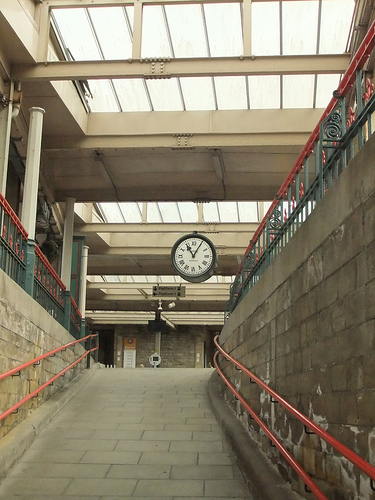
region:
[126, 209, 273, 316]
A large clock hanging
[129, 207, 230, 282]
the clock arrows are black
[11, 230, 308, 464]
this is a ramp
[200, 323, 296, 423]
the rails are red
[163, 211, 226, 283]
the numbers are roman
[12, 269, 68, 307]
fence is green and red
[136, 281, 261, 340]
this is a train station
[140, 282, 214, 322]
signs to the platforms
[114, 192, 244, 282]
the windows are skylights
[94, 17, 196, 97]
steel beams are tan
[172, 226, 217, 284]
The hanging clock that is black and white.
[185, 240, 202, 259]
The hands on the hanging clock.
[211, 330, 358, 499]
The red railing on the right side of the walkway.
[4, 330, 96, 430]
The red railing on the left side of the walkway.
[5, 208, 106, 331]
The red and green wrought iron gate on the left side platform.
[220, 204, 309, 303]
The red and green wrought iron gate on the right side of the top platform.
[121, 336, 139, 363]
The orange and white sign against the wall.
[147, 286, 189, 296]
The hanging black and white sign behind the clock.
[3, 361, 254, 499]
The walkway leading up to the clock.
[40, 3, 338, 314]
The skylight ceiling for natural lighting.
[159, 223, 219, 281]
A clock hanging down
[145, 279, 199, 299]
Sign to direct people to platforms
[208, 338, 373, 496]
red hand railing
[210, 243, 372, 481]
A stone wall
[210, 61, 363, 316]
green and red hand railing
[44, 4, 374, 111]
Windows on the roof to let in light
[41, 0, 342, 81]
A steel support beam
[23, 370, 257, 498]
a ramp leading to the main level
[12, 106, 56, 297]
a support column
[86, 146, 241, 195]
lights on the ceiling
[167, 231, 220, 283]
Clock hanging from above.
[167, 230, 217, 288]
The clock face is white.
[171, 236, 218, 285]
Numbers on the clock are black.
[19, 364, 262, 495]
Concrete block walkway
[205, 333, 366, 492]
Hand rails are red.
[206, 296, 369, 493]
Walls made of concrete block.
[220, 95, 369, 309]
Metal fence lining the wall.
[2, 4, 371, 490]
Nobody shown in the photo.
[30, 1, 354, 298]
Photo taken during the day.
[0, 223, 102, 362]
The fencing is green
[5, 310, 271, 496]
a walkway leading upward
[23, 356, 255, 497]
the walkway is made of bricks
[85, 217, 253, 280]
a clock hangs from an above beam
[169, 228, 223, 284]
the clock shows the time of 11:05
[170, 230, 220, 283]
the clock has roman numerals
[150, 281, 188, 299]
a directional sign in the background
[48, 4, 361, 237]
the skylight has long panels of windows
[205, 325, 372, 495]
the safety bar along the walkway is red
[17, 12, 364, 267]
metal beams above the walkway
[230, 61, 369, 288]
the metal fencing is green and red